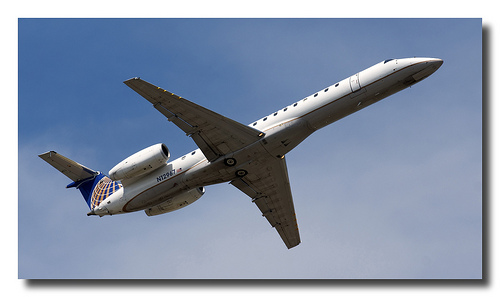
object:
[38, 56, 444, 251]
plane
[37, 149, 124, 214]
tail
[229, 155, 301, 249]
wing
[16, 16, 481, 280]
sky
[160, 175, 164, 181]
writing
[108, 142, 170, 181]
engine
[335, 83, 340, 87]
windows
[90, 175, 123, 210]
logo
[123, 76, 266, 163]
wing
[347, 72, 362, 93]
door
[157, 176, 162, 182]
letter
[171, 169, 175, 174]
numbers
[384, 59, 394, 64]
windshield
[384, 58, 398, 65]
cockpit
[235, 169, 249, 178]
wheels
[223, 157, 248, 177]
landing gear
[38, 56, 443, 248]
airplane